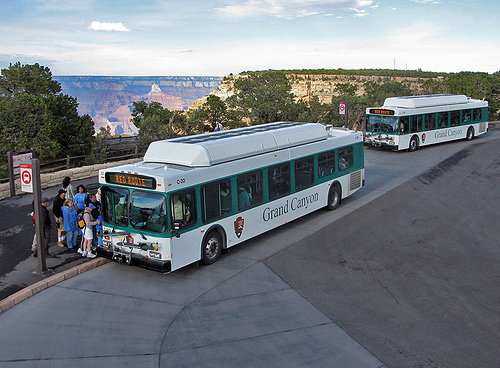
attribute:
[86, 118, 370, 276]
bus — at grand canyon, grand canyon, green, white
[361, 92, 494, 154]
bus — at grand canyon, green, white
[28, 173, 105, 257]
people — waiting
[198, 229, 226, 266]
tire — large, black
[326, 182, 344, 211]
tire — rear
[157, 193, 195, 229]
driver — in seat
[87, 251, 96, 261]
shoes — white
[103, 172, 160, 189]
sign — red route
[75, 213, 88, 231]
backpack — black, yellow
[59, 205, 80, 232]
jacket — blue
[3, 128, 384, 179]
overlook — grand canyon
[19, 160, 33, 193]
sign — red, white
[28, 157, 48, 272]
signpost — brown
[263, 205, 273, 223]
letter — green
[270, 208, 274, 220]
letter — green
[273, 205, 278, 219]
letter — green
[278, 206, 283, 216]
letter — green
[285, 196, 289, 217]
letter — green